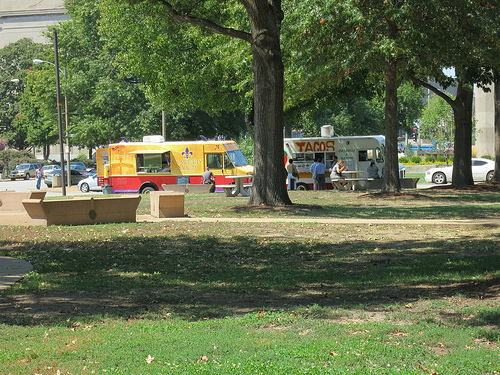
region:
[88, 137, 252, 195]
a red and yellow food truck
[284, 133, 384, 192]
a white taco food truck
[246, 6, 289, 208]
a wide bare tree tunk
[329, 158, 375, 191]
person sitting at a table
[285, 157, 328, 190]
people standing in line for food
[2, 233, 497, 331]
shadow from a tree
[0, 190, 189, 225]
benches in a park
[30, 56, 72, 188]
a lamp post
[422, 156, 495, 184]
a white car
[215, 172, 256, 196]
an empty picnic table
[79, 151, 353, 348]
the grass is green and lush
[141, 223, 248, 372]
the grass is green and lush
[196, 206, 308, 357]
the grass is green and lush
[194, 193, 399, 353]
the grass is green and lush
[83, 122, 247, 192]
yellow truck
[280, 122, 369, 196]
white taco truck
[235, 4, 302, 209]
tall thick tree in front of trucks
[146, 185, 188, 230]
brown bench in front of truck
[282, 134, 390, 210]
people in front of white truck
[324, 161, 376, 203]
bench near white truck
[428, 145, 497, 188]
white car near white truck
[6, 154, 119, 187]
parking lot behind yellow truck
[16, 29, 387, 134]
trees behind trucks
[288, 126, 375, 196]
red letters on white truck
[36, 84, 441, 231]
food trucks in a park selling food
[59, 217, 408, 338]
large shadow cast by big tree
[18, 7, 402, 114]
green leaves are in the background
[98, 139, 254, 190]
yellow and red truck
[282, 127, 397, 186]
white truck sells tacos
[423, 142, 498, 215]
white car parked on street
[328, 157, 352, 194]
person sitting at table and eating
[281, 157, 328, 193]
people are in line at the taco truck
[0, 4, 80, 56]
gray building in background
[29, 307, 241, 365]
grass with leaves on the ground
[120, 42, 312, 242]
the tree is green and visible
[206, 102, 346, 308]
the tree is green and visible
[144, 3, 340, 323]
the tree is green and visible